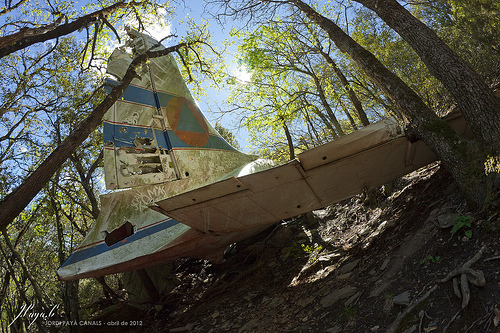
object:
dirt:
[91, 262, 498, 324]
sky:
[0, 0, 370, 80]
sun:
[187, 26, 288, 88]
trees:
[0, 0, 237, 233]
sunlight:
[100, 7, 219, 73]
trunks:
[286, 0, 500, 212]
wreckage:
[49, 24, 500, 281]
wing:
[148, 89, 500, 236]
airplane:
[54, 26, 500, 282]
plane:
[54, 26, 500, 284]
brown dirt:
[253, 225, 500, 333]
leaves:
[447, 0, 499, 53]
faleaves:
[221, 34, 307, 116]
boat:
[53, 24, 500, 282]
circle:
[164, 95, 212, 147]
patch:
[340, 202, 408, 258]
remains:
[54, 23, 500, 282]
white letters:
[1, 299, 145, 333]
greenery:
[413, 218, 469, 268]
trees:
[194, 0, 500, 214]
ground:
[0, 165, 499, 333]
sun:
[273, 194, 391, 286]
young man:
[99, 74, 238, 152]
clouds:
[76, 8, 258, 103]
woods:
[1, 1, 497, 333]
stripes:
[101, 77, 236, 150]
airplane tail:
[57, 29, 500, 282]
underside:
[146, 114, 464, 236]